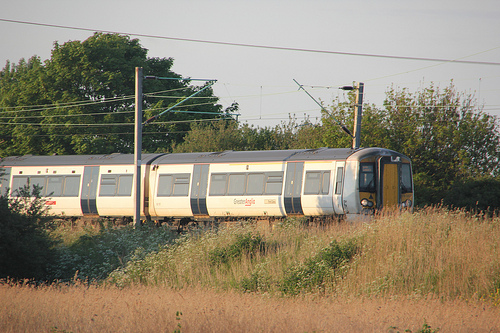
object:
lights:
[360, 196, 376, 208]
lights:
[401, 197, 413, 204]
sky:
[1, 2, 499, 177]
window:
[155, 170, 193, 202]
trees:
[0, 29, 244, 155]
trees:
[159, 76, 499, 219]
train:
[0, 146, 417, 223]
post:
[128, 69, 146, 231]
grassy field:
[6, 215, 499, 331]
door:
[75, 163, 102, 218]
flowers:
[43, 214, 221, 294]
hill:
[3, 217, 499, 304]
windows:
[355, 163, 382, 193]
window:
[303, 170, 330, 197]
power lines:
[0, 18, 499, 137]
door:
[188, 159, 213, 222]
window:
[261, 174, 283, 194]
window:
[250, 174, 267, 193]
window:
[221, 171, 244, 198]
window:
[209, 173, 231, 193]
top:
[2, 147, 370, 167]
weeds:
[22, 213, 465, 330]